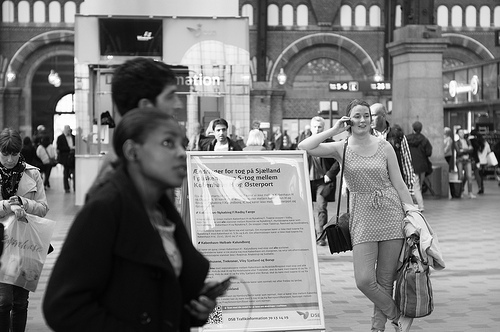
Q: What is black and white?
A: Picture.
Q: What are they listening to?
A: Music.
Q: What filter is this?
A: Black and white.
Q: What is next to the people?
A: Sign.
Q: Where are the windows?
A: Top.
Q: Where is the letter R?
A: On the sign.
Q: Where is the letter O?
A: On the sign.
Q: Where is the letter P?
A: On the sign.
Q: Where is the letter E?
A: On the sign.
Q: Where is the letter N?
A: On the sign.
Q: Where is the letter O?
A: On the sign.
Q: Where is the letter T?
A: On the sign.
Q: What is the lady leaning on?
A: Sign.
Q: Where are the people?
A: Train station.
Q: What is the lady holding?
A: Cell phone.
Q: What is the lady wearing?
A: A dress.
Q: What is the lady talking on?
A: Cell phone.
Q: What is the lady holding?
A: Bag.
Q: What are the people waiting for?
A: Train.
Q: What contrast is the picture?
A: Black and white.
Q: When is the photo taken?
A: Daytime.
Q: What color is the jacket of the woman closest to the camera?
A: Black.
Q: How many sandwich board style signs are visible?
A: One.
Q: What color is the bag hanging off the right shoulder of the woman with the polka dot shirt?
A: Black.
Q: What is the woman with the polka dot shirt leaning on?
A: Sandwich board sign.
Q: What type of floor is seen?
A: Tile.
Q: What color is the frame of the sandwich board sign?
A: White.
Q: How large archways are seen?
A: Three.